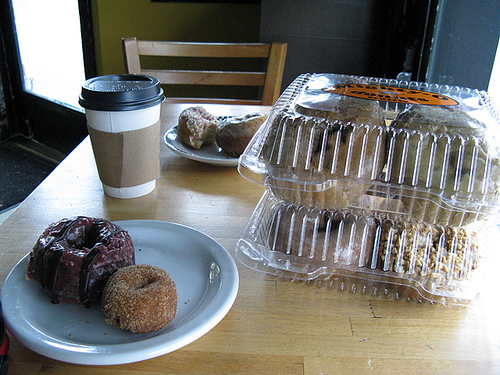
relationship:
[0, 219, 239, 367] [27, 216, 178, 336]
plate has donuts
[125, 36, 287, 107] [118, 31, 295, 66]
back has top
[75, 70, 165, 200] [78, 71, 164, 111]
coffee cup has black lid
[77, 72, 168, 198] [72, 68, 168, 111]
coffee cup has top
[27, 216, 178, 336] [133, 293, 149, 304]
donuts has sugar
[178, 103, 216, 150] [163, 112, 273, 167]
donut on plate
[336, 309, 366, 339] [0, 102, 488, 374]
mark on table top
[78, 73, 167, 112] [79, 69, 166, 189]
black lid on coffee cup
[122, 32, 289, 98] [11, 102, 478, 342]
wood chair around table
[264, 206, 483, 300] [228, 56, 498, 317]
donuts in package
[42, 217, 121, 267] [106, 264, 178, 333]
sugar on doughnut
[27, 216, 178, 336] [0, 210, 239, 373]
donuts on plate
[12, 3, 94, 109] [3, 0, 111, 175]
window on door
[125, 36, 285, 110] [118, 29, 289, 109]
back of chair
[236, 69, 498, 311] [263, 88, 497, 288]
boxes contain donuts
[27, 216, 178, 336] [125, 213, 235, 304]
donuts on plate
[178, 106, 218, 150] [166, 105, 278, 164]
donut on plate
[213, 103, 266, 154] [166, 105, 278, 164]
doughtnut on plate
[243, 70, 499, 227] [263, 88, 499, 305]
container contains donuts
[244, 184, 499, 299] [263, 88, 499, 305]
container contains donuts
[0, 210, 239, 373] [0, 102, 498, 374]
plate on table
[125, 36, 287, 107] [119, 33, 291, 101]
back on chair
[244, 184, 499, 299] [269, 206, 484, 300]
container filled with donuts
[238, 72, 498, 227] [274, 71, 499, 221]
container filled with doughnuts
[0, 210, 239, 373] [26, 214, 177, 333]
plate with treats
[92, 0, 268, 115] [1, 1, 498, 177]
paint on wall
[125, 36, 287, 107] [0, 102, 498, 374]
back by table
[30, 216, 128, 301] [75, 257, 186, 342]
frosting on donut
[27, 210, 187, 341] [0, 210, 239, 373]
donuts on plate